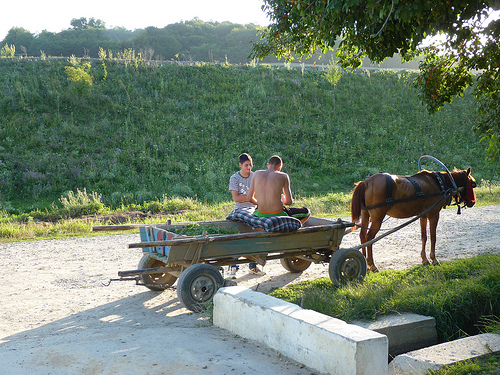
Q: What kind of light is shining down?
A: Sunlight.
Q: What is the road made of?
A: Gravel.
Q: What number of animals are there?
A: One.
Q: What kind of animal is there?
A: A horse.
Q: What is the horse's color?
A: Brown.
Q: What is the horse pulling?
A: A cart.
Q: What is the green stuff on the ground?
A: Grass.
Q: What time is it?
A: Afternoon.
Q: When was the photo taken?
A: During the daytime.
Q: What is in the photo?
A: A horse.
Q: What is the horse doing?
A: Standing.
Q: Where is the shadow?
A: On the ground.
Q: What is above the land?
A: The sky.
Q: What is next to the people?
A: Grass.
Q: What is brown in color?
A: The horse.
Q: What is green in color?
A: The leaves.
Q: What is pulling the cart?
A: Horse.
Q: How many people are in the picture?
A: Two.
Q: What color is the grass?
A: Green.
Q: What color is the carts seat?
A: Blue and white.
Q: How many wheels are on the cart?
A: Four.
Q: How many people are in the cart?
A: One.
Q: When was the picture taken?
A: Daytime.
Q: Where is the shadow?
A: On the ground.